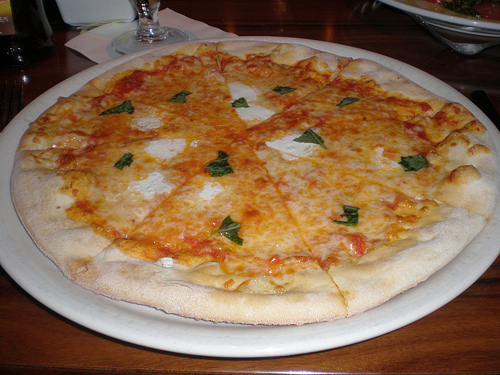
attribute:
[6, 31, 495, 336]
pizza — cheese, artisan, basil topped, old style, large, round, light colored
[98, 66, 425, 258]
cheese — melted, white, yellow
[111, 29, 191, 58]
bottom — round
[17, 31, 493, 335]
crust — homemade, light tan, light dough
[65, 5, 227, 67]
napkin — small, square, white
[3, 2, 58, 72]
bottle — olive oil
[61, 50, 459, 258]
topping — orange, green, leaf, herb, leaves, red sauce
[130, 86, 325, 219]
topping — white, green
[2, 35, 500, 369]
plate — large, white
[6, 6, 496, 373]
table — wooden, brown, shiny